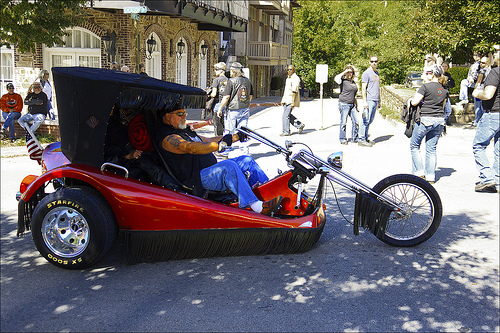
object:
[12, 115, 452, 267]
motorcycle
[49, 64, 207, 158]
shelf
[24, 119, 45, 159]
us flag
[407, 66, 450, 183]
woman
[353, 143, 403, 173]
ground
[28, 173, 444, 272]
3 wheeled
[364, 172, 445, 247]
front wheel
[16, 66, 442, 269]
bike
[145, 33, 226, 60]
lanterns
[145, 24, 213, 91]
arches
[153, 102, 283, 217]
biker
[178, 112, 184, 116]
glasses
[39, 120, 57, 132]
wall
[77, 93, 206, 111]
fringe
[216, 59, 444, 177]
people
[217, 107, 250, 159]
jeans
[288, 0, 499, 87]
trees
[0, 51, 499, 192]
crowd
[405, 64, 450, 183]
lady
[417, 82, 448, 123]
shirt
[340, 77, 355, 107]
shirt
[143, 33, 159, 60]
street lamp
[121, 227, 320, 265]
fringe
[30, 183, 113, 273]
tire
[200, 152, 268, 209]
jeans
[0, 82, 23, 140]
woman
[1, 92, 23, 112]
shirt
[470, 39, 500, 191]
person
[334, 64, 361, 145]
person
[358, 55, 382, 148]
person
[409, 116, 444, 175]
jeans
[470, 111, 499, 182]
jeans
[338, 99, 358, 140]
jeans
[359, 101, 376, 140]
jeans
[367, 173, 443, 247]
wheel